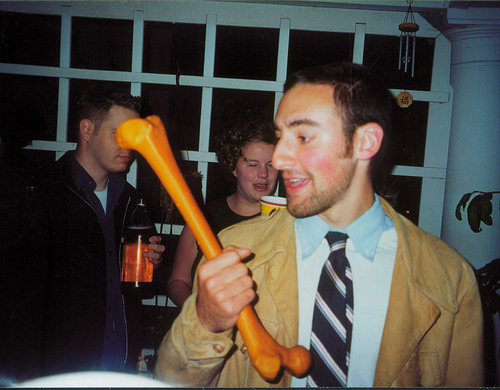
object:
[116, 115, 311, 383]
bone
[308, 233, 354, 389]
neck tie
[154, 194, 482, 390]
jacket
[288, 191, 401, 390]
shirt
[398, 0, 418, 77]
windchimes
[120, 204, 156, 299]
bottle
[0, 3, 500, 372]
wall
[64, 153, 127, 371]
shirt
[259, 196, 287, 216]
cup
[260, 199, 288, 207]
red stripe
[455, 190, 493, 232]
branch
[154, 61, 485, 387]
man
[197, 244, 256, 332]
fist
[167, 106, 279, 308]
woman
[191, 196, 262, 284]
shirt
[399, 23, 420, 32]
disc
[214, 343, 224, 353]
button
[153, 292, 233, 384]
sleeve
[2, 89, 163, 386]
man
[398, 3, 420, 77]
column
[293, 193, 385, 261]
collar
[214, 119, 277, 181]
hair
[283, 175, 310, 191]
mouth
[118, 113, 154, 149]
knob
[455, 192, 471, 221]
leaf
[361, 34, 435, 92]
window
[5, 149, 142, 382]
jacket